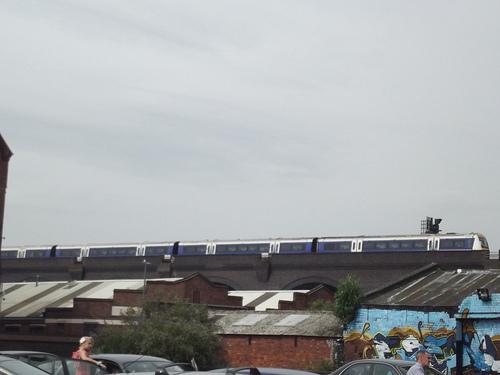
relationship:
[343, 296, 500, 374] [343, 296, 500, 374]
graffiti on graffiti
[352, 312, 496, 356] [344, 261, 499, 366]
graffiti on building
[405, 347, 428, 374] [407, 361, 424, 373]
man wearing shirt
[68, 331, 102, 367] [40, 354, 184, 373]
woman by car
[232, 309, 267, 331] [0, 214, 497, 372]
square on building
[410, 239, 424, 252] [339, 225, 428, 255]
window on train car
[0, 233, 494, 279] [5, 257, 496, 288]
train on bridge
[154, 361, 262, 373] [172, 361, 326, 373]
rack on top of car